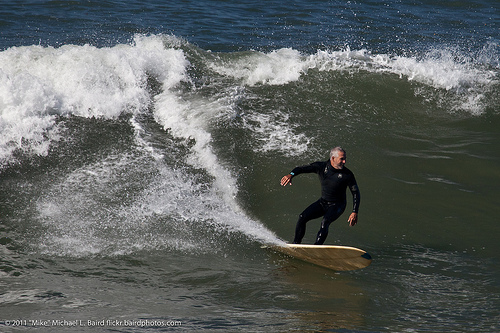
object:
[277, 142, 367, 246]
man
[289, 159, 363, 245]
wetsuit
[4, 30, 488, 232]
waves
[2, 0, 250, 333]
ocean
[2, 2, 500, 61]
water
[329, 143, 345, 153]
hair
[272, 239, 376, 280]
surfboard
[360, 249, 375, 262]
tip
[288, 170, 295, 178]
bracelet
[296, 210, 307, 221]
knees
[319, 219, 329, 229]
knees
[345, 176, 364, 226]
arms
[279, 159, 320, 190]
arms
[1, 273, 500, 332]
water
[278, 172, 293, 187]
hand